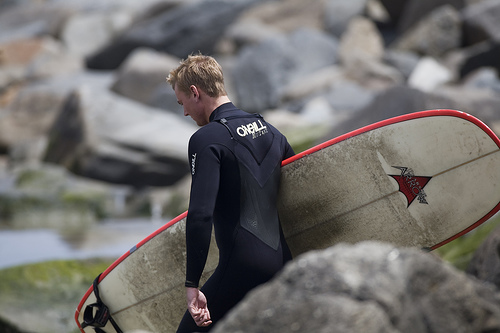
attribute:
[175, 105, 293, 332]
swimsuit — black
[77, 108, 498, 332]
surfboard — dirty, white, red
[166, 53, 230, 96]
hair — blond, short, brown, dirty blonde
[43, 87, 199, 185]
rock — pictured, large, gray, huge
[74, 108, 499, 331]
frame — red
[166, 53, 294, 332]
surfer — white, walking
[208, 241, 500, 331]
boulder — large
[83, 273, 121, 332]
strap — black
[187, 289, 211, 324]
left hand — curled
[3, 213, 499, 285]
grass — green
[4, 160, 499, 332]
ground — pictured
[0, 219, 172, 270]
water — blurry